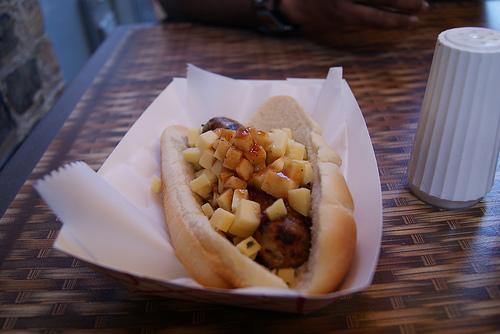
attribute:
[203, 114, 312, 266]
hot dog — here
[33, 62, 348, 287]
paper — white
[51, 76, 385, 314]
tray — paper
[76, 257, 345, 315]
design — striped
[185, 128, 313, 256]
topping — cubed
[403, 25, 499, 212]
salt shaker — here, white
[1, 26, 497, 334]
table — brown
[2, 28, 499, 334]
pattern — wicker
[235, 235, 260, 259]
cheese — white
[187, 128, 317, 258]
cheese — white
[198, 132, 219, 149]
fruit piece — here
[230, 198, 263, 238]
fruit piece — here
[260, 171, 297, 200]
fruit piece — here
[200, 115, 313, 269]
sausage — here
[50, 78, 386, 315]
plate — white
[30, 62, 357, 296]
towel — paper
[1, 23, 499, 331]
mat — brown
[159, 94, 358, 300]
food — here